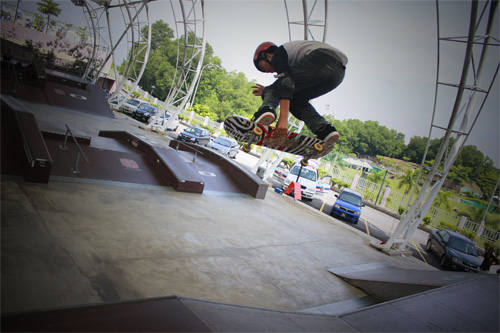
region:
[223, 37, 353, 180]
boy is holding skate board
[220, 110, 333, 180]
skate board is black and white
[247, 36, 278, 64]
helmet on boy is red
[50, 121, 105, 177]
railing is in skate park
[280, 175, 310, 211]
orange sign is near parking lot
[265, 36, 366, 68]
boys shirt is grey and black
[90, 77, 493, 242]
fence in back ground is metal and cement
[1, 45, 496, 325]
skate park is brown and tan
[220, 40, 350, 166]
skate boarder is in the air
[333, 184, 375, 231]
vehicle is blue in color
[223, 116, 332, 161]
black red and white skateboard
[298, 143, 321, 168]
yellow tires on skateboard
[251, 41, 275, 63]
red helmet on head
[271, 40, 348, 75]
black and white shirt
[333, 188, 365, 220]
blue car in lot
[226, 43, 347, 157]
man doing skateboard tricks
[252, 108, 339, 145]
black and white sneakers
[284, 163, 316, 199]
white truck in lot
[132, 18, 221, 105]
trees with green leaves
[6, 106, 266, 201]
brown wood skateboard ramp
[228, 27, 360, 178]
boy on a skateboard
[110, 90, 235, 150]
cars parked in the distance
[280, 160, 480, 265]
cars parked in the distance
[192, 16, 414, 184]
boy on a skateboard in the air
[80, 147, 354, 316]
skateboard ramps made of wood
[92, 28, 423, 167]
boy on a skateboard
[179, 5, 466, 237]
boy on a skateboard with a helmet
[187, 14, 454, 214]
boy on a skateboard holding his board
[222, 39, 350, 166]
skateboarder on a skateboard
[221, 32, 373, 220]
skateboarder on his skateboard in the air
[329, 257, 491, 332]
gray concrete jumping ramp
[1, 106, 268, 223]
different jumping platforms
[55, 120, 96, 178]
gray metal railing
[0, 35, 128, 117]
brown metal jumping platform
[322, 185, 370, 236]
a blue car in a parkingspot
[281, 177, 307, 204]
orange collapsible sign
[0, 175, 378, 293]
dirty looking concrete flooring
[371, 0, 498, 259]
rounded metal poling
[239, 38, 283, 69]
Person wearing red helmet.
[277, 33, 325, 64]
Person wearing t-shirt.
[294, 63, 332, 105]
Person wearing black pants.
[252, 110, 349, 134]
Person wearing black and white shoes.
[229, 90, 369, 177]
Person doing trick on skateboard.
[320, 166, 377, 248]
Blue car parked in parking spot.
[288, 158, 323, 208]
White car parked in parking spot.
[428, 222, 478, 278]
Dark colored car parked in parking spot.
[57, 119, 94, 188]
Silver railing sticking out of concrete.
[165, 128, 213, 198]
Silver railing sticking out of concrete.